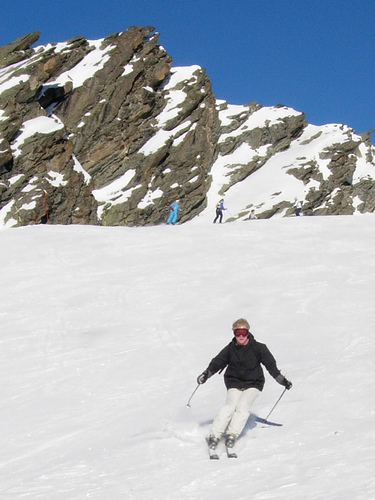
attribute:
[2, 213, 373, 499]
snow — white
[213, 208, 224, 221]
pants — black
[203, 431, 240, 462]
skis — silver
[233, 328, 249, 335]
goggles — red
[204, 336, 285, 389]
black coat — winter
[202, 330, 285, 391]
jacket — navy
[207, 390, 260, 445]
pants — white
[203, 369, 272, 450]
pants — white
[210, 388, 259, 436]
pants — white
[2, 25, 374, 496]
landscape — hilly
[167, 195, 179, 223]
person — light blue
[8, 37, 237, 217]
rocky edge — large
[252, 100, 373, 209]
rocky edge — large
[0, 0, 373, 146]
sky — blue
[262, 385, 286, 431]
ski pole — long, silver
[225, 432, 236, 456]
ski boot — silver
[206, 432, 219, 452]
ski boot — silver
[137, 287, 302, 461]
man — skiing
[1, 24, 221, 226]
rock — gray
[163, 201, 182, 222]
ski suit — blue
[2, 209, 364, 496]
area — large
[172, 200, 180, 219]
ski suit — light blue